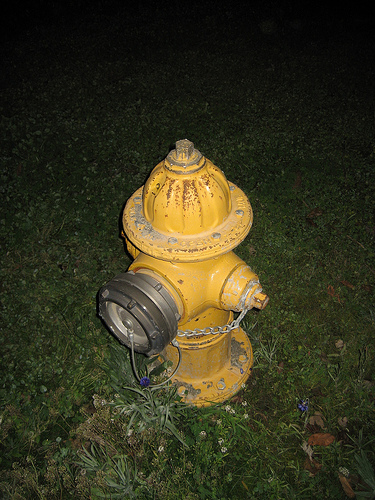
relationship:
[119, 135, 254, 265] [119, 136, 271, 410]
cover on hydrant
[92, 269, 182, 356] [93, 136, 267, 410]
cover on hydrant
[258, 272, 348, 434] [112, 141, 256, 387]
grass by hydrant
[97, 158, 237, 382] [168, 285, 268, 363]
hydrant with chain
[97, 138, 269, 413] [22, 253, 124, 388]
hydrant in grass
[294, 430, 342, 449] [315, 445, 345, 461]
leaf on grass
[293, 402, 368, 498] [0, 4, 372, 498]
leaves are in grass